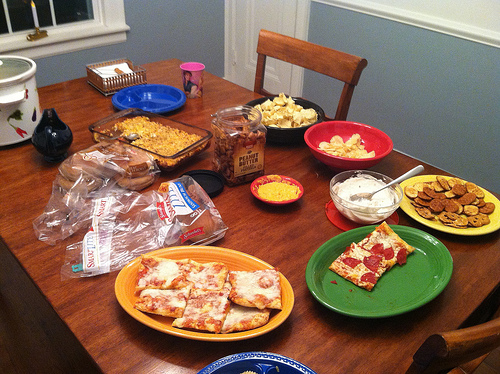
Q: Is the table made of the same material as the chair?
A: Yes, both the table and the chair are made of wood.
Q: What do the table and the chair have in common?
A: The material, both the table and the chair are wooden.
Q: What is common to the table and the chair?
A: The material, both the table and the chair are wooden.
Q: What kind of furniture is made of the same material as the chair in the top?
A: The table is made of the same material as the chair.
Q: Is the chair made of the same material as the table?
A: Yes, both the chair and the table are made of wood.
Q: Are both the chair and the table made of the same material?
A: Yes, both the chair and the table are made of wood.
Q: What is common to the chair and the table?
A: The material, both the chair and the table are wooden.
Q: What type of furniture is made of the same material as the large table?
A: The chair is made of the same material as the table.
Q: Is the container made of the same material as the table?
A: No, the container is made of plastic and the table is made of wood.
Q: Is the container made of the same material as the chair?
A: No, the container is made of plastic and the chair is made of wood.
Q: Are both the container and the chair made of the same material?
A: No, the container is made of plastic and the chair is made of wood.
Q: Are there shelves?
A: No, there are no shelves.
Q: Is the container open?
A: Yes, the container is open.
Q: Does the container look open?
A: Yes, the container is open.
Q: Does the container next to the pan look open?
A: Yes, the container is open.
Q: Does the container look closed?
A: No, the container is open.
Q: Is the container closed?
A: No, the container is open.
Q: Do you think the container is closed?
A: No, the container is open.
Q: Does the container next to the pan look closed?
A: No, the container is open.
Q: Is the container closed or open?
A: The container is open.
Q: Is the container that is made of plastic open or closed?
A: The container is open.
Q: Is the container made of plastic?
A: Yes, the container is made of plastic.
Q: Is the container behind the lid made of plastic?
A: Yes, the container is made of plastic.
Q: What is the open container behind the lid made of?
A: The container is made of plastic.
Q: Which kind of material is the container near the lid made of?
A: The container is made of plastic.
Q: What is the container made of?
A: The container is made of plastic.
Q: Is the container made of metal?
A: No, the container is made of plastic.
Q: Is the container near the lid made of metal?
A: No, the container is made of plastic.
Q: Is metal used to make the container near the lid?
A: No, the container is made of plastic.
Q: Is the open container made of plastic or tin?
A: The container is made of plastic.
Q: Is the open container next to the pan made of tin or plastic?
A: The container is made of plastic.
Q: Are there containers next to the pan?
A: Yes, there is a container next to the pan.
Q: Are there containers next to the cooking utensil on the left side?
A: Yes, there is a container next to the pan.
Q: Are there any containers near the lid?
A: Yes, there is a container near the lid.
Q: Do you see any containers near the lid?
A: Yes, there is a container near the lid.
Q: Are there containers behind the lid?
A: Yes, there is a container behind the lid.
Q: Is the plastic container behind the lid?
A: Yes, the container is behind the lid.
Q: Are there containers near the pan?
A: Yes, there is a container near the pan.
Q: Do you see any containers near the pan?
A: Yes, there is a container near the pan.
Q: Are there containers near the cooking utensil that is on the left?
A: Yes, there is a container near the pan.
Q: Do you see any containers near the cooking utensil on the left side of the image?
A: Yes, there is a container near the pan.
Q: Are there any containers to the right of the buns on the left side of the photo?
A: Yes, there is a container to the right of the buns.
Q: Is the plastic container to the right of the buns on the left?
A: Yes, the container is to the right of the buns.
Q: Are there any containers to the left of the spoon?
A: Yes, there is a container to the left of the spoon.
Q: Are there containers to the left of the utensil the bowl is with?
A: Yes, there is a container to the left of the spoon.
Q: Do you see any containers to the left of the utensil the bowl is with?
A: Yes, there is a container to the left of the spoon.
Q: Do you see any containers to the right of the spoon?
A: No, the container is to the left of the spoon.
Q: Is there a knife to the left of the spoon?
A: No, there is a container to the left of the spoon.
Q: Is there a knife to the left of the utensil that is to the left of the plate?
A: No, there is a container to the left of the spoon.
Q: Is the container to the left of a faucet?
A: No, the container is to the left of the spoon.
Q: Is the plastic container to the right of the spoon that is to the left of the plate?
A: No, the container is to the left of the spoon.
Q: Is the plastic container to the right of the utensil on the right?
A: No, the container is to the left of the spoon.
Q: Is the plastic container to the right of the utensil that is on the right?
A: No, the container is to the left of the spoon.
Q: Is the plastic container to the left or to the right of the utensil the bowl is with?
A: The container is to the left of the spoon.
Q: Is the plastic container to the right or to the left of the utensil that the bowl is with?
A: The container is to the left of the spoon.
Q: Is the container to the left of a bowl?
A: Yes, the container is to the left of a bowl.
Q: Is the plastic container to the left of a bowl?
A: Yes, the container is to the left of a bowl.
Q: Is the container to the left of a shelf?
A: No, the container is to the left of a bowl.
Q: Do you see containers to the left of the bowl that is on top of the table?
A: Yes, there is a container to the left of the bowl.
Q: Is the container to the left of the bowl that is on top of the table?
A: Yes, the container is to the left of the bowl.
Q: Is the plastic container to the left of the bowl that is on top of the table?
A: Yes, the container is to the left of the bowl.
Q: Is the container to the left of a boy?
A: No, the container is to the left of the bowl.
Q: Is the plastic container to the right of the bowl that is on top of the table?
A: No, the container is to the left of the bowl.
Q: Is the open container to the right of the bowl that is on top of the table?
A: No, the container is to the left of the bowl.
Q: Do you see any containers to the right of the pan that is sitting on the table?
A: Yes, there is a container to the right of the pan.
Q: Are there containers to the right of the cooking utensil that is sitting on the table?
A: Yes, there is a container to the right of the pan.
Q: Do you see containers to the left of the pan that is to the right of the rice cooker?
A: No, the container is to the right of the pan.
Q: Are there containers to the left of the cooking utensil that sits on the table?
A: No, the container is to the right of the pan.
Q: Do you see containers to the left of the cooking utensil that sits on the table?
A: No, the container is to the right of the pan.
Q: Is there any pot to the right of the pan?
A: No, there is a container to the right of the pan.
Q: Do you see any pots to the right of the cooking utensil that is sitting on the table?
A: No, there is a container to the right of the pan.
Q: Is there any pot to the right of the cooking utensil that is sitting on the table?
A: No, there is a container to the right of the pan.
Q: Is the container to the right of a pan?
A: Yes, the container is to the right of a pan.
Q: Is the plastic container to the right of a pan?
A: Yes, the container is to the right of a pan.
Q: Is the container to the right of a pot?
A: No, the container is to the right of a pan.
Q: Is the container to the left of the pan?
A: No, the container is to the right of the pan.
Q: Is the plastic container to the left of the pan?
A: No, the container is to the right of the pan.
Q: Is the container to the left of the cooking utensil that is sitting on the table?
A: No, the container is to the right of the pan.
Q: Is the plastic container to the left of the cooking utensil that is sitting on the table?
A: No, the container is to the right of the pan.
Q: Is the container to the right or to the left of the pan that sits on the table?
A: The container is to the right of the pan.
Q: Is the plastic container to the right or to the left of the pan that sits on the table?
A: The container is to the right of the pan.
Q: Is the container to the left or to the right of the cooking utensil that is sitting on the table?
A: The container is to the right of the pan.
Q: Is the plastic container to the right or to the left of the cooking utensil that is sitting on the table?
A: The container is to the right of the pan.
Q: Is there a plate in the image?
A: Yes, there is a plate.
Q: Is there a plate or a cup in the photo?
A: Yes, there is a plate.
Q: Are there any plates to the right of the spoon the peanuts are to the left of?
A: Yes, there is a plate to the right of the spoon.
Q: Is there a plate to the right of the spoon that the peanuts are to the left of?
A: Yes, there is a plate to the right of the spoon.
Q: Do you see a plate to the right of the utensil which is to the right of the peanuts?
A: Yes, there is a plate to the right of the spoon.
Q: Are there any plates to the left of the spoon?
A: No, the plate is to the right of the spoon.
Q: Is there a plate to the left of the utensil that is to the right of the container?
A: No, the plate is to the right of the spoon.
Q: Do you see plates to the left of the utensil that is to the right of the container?
A: No, the plate is to the right of the spoon.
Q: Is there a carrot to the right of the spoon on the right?
A: No, there is a plate to the right of the spoon.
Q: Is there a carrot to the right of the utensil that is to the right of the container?
A: No, there is a plate to the right of the spoon.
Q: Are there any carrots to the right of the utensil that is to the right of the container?
A: No, there is a plate to the right of the spoon.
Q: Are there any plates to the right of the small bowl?
A: Yes, there is a plate to the right of the bowl.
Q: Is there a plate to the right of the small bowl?
A: Yes, there is a plate to the right of the bowl.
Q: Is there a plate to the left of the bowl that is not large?
A: No, the plate is to the right of the bowl.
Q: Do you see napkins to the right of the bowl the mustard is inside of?
A: No, there is a plate to the right of the bowl.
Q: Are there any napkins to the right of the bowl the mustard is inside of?
A: No, there is a plate to the right of the bowl.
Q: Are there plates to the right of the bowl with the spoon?
A: Yes, there is a plate to the right of the bowl.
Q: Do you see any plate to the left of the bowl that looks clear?
A: No, the plate is to the right of the bowl.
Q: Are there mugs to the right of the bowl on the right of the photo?
A: No, there is a plate to the right of the bowl.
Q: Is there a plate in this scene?
A: Yes, there is a plate.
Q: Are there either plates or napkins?
A: Yes, there is a plate.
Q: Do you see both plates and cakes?
A: No, there is a plate but no cakes.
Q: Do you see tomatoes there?
A: No, there are no tomatoes.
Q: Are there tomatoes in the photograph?
A: No, there are no tomatoes.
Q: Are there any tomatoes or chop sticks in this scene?
A: No, there are no tomatoes or chop sticks.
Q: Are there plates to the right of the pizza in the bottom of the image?
A: Yes, there is a plate to the right of the pizza.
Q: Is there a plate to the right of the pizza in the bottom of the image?
A: Yes, there is a plate to the right of the pizza.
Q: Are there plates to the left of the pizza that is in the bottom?
A: No, the plate is to the right of the pizza.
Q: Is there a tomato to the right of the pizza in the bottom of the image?
A: No, there is a plate to the right of the pizza.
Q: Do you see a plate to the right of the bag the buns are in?
A: Yes, there is a plate to the right of the bag.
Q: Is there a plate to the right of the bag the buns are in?
A: Yes, there is a plate to the right of the bag.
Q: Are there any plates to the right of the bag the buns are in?
A: Yes, there is a plate to the right of the bag.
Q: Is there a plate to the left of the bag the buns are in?
A: No, the plate is to the right of the bag.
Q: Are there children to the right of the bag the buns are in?
A: No, there is a plate to the right of the bag.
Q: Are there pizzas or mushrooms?
A: Yes, there is a pizza.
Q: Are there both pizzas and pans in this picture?
A: Yes, there are both a pizza and a pan.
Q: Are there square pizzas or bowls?
A: Yes, there is a square pizza.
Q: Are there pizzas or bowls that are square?
A: Yes, the pizza is square.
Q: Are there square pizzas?
A: Yes, there is a square pizza.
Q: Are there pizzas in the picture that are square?
A: Yes, there is a pizza that is square.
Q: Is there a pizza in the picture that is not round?
A: Yes, there is a square pizza.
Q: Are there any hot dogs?
A: No, there are no hot dogs.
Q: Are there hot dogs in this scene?
A: No, there are no hot dogs.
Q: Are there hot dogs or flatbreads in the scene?
A: No, there are no hot dogs or flatbreads.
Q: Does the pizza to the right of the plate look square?
A: Yes, the pizza is square.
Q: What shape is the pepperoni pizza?
A: The pizza is square.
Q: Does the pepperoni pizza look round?
A: No, the pizza is square.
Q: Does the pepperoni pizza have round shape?
A: No, the pizza is square.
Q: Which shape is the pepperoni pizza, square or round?
A: The pizza is square.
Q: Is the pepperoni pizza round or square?
A: The pizza is square.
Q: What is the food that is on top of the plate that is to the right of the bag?
A: The food is a pizza.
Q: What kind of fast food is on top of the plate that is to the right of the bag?
A: The food is a pizza.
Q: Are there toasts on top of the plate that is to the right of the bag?
A: No, there is a pizza on top of the plate.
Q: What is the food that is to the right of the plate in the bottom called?
A: The food is a pizza.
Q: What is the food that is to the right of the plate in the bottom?
A: The food is a pizza.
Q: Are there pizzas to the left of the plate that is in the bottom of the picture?
A: No, the pizza is to the right of the plate.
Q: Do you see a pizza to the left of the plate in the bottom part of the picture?
A: No, the pizza is to the right of the plate.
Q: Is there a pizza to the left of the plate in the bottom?
A: No, the pizza is to the right of the plate.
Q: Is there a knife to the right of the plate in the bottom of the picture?
A: No, there is a pizza to the right of the plate.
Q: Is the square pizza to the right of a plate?
A: Yes, the pizza is to the right of a plate.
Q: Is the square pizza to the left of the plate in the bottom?
A: No, the pizza is to the right of the plate.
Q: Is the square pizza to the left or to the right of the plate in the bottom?
A: The pizza is to the right of the plate.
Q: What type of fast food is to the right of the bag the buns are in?
A: The food is a pizza.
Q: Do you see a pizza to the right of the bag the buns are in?
A: Yes, there is a pizza to the right of the bag.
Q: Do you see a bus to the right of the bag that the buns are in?
A: No, there is a pizza to the right of the bag.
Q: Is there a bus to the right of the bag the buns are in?
A: No, there is a pizza to the right of the bag.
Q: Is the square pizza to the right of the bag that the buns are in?
A: Yes, the pizza is to the right of the bag.